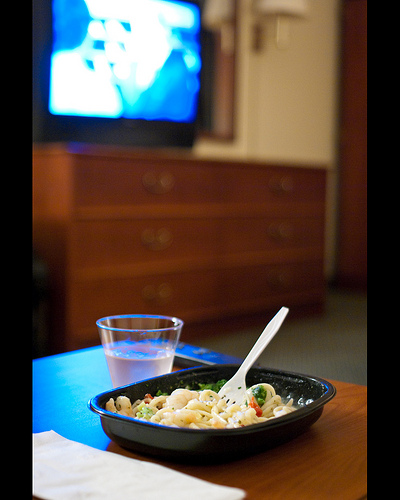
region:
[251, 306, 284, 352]
handle of a spoon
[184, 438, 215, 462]
outer part of a dish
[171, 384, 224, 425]
part of some food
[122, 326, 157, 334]
edge of a cup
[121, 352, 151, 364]
water level in a cup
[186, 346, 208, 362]
part of a remote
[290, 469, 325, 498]
part of a wooden table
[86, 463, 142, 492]
part of white cloth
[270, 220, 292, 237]
handle of a cupboard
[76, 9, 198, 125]
part of a television screen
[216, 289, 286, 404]
A white plastic fork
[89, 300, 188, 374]
A clear plastic cup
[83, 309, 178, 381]
A cup of water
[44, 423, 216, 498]
A white napkin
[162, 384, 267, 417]
Noodles and vegetables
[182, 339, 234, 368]
A remote control for a tv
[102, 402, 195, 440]
The edge of a black plastic bowl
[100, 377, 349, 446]
A black plastic bowl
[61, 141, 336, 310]
A dresser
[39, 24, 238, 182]
A television on a dresser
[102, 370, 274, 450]
one bowl is seen.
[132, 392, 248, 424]
noodles is in bowl.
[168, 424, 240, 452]
bowl is black color.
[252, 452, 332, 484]
table is brown color.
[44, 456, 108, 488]
tissue paper is white color.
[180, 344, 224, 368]
one remote is on the table.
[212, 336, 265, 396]
one fork is in bowl.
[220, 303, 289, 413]
Fork is white color.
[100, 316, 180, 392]
one glass of water in table.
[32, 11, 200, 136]
TV screen is on.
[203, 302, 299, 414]
"A white, plastic fork"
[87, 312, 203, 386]
"A clear plastic cup"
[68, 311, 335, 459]
"Food and drink on a table"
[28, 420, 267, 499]
"The napkins are white"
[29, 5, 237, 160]
"The television is on"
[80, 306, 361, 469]
"The food is in a black container"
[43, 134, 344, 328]
"The dresser is brown"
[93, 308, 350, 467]
"The remote control is beside the drink"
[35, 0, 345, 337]
"The television is on the dresser"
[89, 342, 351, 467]
"Pasta and vegetables"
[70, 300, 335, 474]
pasta and vegetables with drink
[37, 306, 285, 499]
napkin, drink, and meal on tabletop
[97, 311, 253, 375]
remote control near drink on table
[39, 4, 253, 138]
TV is turned on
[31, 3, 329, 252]
TV is setting on top of dresser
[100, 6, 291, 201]
Mirror is behind TV and over dresser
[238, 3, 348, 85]
lamp is on wall next to mirror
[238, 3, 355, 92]
lamp is turned off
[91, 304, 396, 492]
fork is in pasta dish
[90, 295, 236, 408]
ice is in drink